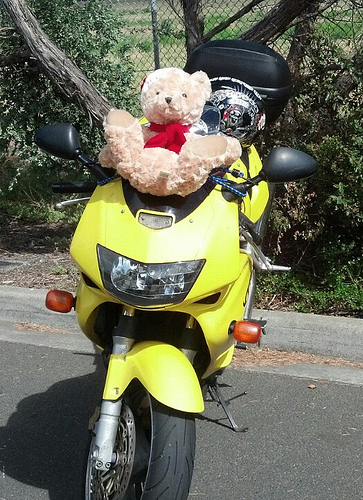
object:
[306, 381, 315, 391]
leaves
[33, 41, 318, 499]
motorcycle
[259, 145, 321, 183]
right mirror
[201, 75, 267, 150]
helmet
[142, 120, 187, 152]
scarf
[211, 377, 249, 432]
kickstand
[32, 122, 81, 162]
mirror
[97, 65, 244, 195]
teddy bear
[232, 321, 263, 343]
red light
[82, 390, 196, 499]
wheel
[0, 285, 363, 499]
ground